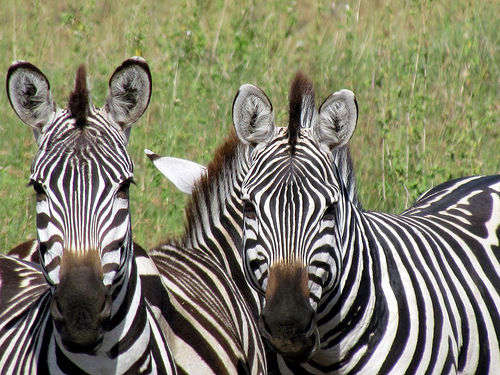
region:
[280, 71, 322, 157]
Mohawk shaped mane on a zebra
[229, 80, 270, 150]
Ear on zebra's head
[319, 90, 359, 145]
Ear on zebra's head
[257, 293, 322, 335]
Black nose on zebra's face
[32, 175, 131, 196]
Two eyes in a zebra's face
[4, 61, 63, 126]
Ear with black outline on zebra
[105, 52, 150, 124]
Ear with black outline on a zebra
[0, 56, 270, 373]
Black and white zebra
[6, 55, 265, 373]
Black and white zebra next to black and white zebra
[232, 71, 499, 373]
Black and white zebra next to black and white zebra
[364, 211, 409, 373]
Black stripe on zebra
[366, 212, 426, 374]
Black stripe on zebra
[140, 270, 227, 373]
Black stripe on zebra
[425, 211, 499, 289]
Black stripe on zebra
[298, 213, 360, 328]
Black stripe on zebra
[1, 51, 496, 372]
Two zebras are in the photo.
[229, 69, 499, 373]
The zebra is black and white.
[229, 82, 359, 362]
The zebra has a brown nose.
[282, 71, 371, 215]
The zebra has mohawk fur.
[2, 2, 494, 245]
There is tall grass in the background.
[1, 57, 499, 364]
The zebras are facing the camera.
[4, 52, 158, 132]
The zebra has round ears.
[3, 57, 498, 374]
The zebras are standing side by side.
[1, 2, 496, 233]
The grass is green and brown.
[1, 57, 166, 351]
The zebra has brown around his ears.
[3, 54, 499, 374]
a group of zebras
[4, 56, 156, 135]
zebra ears perked up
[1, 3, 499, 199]
tall grass in a plane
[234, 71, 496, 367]
a zebra with a mohawk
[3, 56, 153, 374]
a zebra with round ears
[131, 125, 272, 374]
the back of a zebra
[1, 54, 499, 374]
three zebras with furry hair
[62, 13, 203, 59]
yellow and white flowers in grass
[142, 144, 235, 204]
a zebra ear from behind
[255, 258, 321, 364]
a zebras dark mouth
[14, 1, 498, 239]
The grassy field.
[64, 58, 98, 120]
The mane of the left zebra.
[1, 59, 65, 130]
the left ear of the zebra.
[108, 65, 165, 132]
The right ear of the left zebra.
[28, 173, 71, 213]
The left eye of the left zebra.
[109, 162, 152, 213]
The right eye of the left zebra.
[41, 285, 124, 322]
The nostrils of the left zebra.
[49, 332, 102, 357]
The mouth of the left zebra.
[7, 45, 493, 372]
There are two zebras.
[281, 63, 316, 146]
The mane of the right zebra.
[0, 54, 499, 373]
the zebras are standing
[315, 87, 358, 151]
the ear on the zebra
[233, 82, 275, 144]
the ear on the zebra